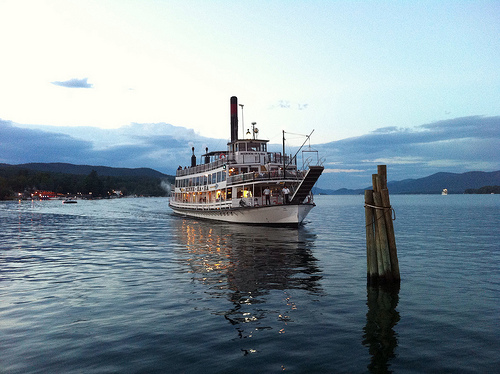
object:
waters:
[14, 264, 90, 302]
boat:
[131, 124, 323, 227]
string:
[363, 199, 388, 212]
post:
[337, 158, 410, 278]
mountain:
[64, 161, 135, 178]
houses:
[24, 185, 59, 205]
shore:
[116, 202, 151, 216]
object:
[434, 184, 467, 198]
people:
[229, 178, 295, 206]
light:
[287, 208, 300, 220]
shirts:
[244, 188, 291, 200]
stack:
[226, 94, 244, 142]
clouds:
[48, 75, 94, 88]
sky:
[246, 9, 380, 94]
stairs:
[288, 164, 332, 203]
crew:
[241, 161, 295, 182]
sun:
[58, 99, 125, 122]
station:
[57, 199, 88, 204]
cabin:
[236, 138, 290, 175]